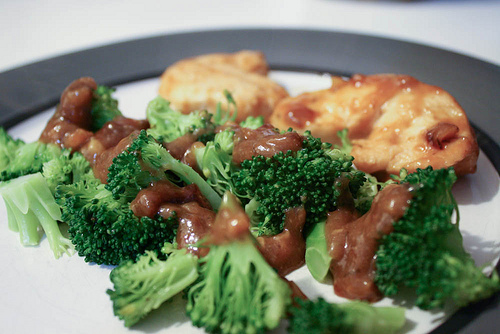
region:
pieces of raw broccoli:
[19, 170, 104, 247]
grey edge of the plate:
[21, 53, 150, 80]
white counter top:
[16, 6, 138, 47]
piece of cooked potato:
[314, 60, 481, 185]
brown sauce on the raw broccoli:
[325, 174, 431, 296]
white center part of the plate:
[0, 262, 101, 332]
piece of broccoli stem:
[5, 166, 65, 241]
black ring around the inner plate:
[6, 105, 39, 130]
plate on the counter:
[9, 23, 202, 150]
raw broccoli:
[410, 248, 475, 302]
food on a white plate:
[5, 59, 499, 331]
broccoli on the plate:
[203, 207, 288, 329]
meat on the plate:
[293, 75, 475, 172]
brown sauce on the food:
[143, 187, 232, 244]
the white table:
[7, 5, 497, 26]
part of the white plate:
[6, 260, 84, 317]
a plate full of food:
[0, 50, 486, 327]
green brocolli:
[16, 154, 149, 266]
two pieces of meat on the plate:
[162, 47, 479, 177]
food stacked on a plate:
[0, 54, 499, 325]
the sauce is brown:
[41, 85, 400, 315]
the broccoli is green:
[21, 153, 150, 279]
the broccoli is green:
[172, 251, 304, 332]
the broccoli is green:
[73, 200, 185, 300]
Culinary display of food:
[0, 0, 498, 332]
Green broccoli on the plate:
[348, 166, 498, 309]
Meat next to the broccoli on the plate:
[155, 46, 484, 183]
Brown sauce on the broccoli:
[321, 178, 411, 300]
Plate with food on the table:
[0, 25, 499, 331]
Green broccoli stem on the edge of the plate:
[2, 170, 74, 260]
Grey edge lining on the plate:
[0, 26, 497, 161]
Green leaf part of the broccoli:
[62, 208, 170, 260]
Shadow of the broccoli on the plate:
[454, 222, 499, 271]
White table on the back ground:
[0, 0, 497, 67]